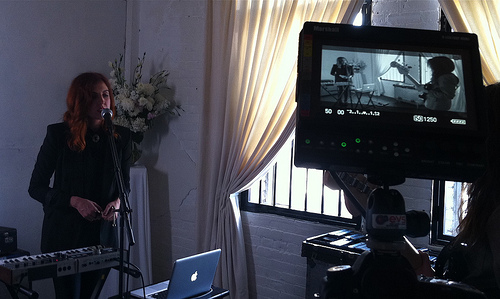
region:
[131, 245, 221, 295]
a gray laptop computer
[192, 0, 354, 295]
a beige curtain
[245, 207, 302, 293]
part of a white brick wall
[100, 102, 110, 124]
a black and gray microphone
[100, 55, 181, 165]
a vase of white flowers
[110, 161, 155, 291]
a long white cloth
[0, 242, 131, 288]
part of a keyboard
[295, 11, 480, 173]
a small black t.v.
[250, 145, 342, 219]
part of a window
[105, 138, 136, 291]
part of a microphone stand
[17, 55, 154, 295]
the woman is dressed in black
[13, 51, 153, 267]
she has wavy hair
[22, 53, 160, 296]
she has red hair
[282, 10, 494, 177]
the monitor displays what a camera is recording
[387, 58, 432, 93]
the fret board of a guitar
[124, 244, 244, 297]
an Apple laptop computer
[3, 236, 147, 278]
an electric keyboard set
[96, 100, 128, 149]
a black and silver microphone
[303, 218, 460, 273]
a xylophone set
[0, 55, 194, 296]
the woman is a singer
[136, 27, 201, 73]
white brick on wall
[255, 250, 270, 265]
white brick on wall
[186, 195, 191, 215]
white brick on wall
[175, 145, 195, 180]
white brick on wall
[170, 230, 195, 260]
white brick on wall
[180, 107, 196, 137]
white brick on wall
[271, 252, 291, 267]
white brick on wall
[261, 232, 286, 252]
white brick on wall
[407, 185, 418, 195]
white brick on wall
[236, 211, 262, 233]
white brick on wall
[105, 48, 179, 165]
An arrangement of white flowers.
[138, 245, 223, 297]
A laptop computer that is open.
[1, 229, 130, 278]
An electronic musical keyboard.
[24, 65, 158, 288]
Woman singing into a microphone.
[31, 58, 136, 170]
A woman with red hair.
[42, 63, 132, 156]
A woman with long hair.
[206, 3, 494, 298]
Floor length curtains on the window.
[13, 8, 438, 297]
The walls are made of white brick.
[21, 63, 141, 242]
The woman is wearing a long black jacket.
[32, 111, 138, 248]
A long sleeve jacket.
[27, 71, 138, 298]
Woman standing at a microphone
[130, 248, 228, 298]
Laptop computer on a computer stand.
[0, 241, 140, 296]
Electronic keyboard is set up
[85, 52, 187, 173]
Bouquet of flowers in the corner of the room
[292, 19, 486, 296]
TV camera with a picture of two people in the room.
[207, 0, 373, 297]
Curtains hanging from the window.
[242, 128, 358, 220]
Bars installed on the window.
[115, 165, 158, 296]
Stand for flower bouquet in the corner.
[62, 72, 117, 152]
brown hair on the head of a woman.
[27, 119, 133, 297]
Black clothing worn by a woman.